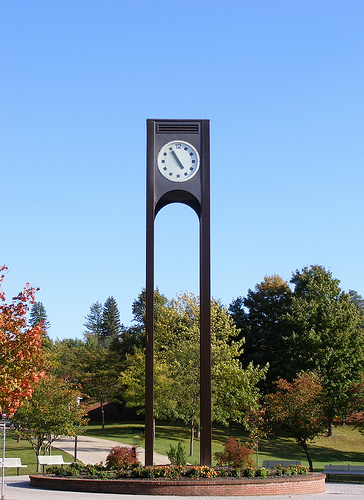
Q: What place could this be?
A: It is a park.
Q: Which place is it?
A: It is a park.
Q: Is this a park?
A: Yes, it is a park.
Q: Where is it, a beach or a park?
A: It is a park.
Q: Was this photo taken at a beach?
A: No, the picture was taken in a park.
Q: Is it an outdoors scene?
A: Yes, it is outdoors.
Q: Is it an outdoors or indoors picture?
A: It is outdoors.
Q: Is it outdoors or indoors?
A: It is outdoors.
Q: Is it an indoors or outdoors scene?
A: It is outdoors.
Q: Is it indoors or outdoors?
A: It is outdoors.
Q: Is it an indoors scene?
A: No, it is outdoors.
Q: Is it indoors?
A: No, it is outdoors.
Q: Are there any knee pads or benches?
A: Yes, there is a bench.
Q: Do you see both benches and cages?
A: No, there is a bench but no cages.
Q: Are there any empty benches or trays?
A: Yes, there is an empty bench.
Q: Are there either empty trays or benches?
A: Yes, there is an empty bench.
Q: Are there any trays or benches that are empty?
A: Yes, the bench is empty.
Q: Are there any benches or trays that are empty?
A: Yes, the bench is empty.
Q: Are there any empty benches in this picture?
A: Yes, there is an empty bench.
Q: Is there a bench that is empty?
A: Yes, there is a bench that is empty.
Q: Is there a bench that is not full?
A: Yes, there is a empty bench.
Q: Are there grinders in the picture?
A: No, there are no grinders.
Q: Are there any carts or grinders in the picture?
A: No, there are no grinders or carts.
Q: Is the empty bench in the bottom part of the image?
A: Yes, the bench is in the bottom of the image.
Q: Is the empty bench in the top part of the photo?
A: No, the bench is in the bottom of the image.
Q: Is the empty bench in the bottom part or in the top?
A: The bench is in the bottom of the image.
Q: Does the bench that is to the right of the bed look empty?
A: Yes, the bench is empty.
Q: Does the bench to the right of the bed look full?
A: No, the bench is empty.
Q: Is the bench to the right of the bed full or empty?
A: The bench is empty.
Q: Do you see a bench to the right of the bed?
A: Yes, there is a bench to the right of the bed.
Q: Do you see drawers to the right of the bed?
A: No, there is a bench to the right of the bed.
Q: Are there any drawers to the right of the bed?
A: No, there is a bench to the right of the bed.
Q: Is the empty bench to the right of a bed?
A: Yes, the bench is to the right of a bed.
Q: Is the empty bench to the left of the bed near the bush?
A: No, the bench is to the right of the bed.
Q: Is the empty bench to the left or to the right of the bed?
A: The bench is to the right of the bed.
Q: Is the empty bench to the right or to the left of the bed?
A: The bench is to the right of the bed.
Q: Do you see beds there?
A: Yes, there is a bed.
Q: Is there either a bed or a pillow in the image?
A: Yes, there is a bed.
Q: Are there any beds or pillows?
A: Yes, there is a bed.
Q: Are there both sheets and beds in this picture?
A: No, there is a bed but no sheets.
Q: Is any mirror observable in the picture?
A: No, there are no mirrors.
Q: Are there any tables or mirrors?
A: No, there are no mirrors or tables.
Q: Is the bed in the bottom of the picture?
A: Yes, the bed is in the bottom of the image.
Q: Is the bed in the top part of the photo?
A: No, the bed is in the bottom of the image.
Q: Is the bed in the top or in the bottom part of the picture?
A: The bed is in the bottom of the image.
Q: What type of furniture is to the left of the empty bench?
A: The piece of furniture is a bed.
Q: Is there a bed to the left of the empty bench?
A: Yes, there is a bed to the left of the bench.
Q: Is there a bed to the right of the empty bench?
A: No, the bed is to the left of the bench.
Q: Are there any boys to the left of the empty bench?
A: No, there is a bed to the left of the bench.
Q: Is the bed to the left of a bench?
A: Yes, the bed is to the left of a bench.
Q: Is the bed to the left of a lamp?
A: No, the bed is to the left of a bench.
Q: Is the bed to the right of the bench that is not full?
A: No, the bed is to the left of the bench.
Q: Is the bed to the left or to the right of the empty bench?
A: The bed is to the left of the bench.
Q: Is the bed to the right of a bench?
A: Yes, the bed is to the right of a bench.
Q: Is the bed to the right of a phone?
A: No, the bed is to the right of a bench.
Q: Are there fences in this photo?
A: No, there are no fences.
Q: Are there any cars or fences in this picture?
A: No, there are no fences or cars.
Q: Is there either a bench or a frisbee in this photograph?
A: Yes, there is a bench.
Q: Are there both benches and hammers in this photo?
A: No, there is a bench but no hammers.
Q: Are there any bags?
A: No, there are no bags.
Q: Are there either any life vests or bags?
A: No, there are no bags or life vests.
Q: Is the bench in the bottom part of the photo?
A: Yes, the bench is in the bottom of the image.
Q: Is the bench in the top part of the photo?
A: No, the bench is in the bottom of the image.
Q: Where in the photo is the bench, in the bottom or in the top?
A: The bench is in the bottom of the image.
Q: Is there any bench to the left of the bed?
A: Yes, there is a bench to the left of the bed.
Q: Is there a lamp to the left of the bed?
A: No, there is a bench to the left of the bed.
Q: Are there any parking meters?
A: No, there are no parking meters.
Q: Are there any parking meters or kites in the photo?
A: No, there are no parking meters or kites.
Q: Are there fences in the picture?
A: No, there are no fences.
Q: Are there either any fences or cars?
A: No, there are no fences or cars.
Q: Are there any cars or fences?
A: No, there are no fences or cars.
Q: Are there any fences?
A: No, there are no fences.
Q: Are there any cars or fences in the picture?
A: No, there are no fences or cars.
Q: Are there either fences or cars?
A: No, there are no fences or cars.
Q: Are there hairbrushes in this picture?
A: No, there are no hairbrushes.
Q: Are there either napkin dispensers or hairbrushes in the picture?
A: No, there are no hairbrushes or napkin dispensers.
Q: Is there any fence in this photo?
A: No, there are no fences.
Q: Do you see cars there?
A: No, there are no cars.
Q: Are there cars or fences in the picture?
A: No, there are no cars or fences.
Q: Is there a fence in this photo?
A: No, there are no fences.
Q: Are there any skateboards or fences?
A: No, there are no fences or skateboards.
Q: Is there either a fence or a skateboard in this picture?
A: No, there are no fences or skateboards.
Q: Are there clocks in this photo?
A: Yes, there is a clock.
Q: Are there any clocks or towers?
A: Yes, there is a clock.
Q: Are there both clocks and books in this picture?
A: No, there is a clock but no books.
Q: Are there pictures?
A: No, there are no pictures.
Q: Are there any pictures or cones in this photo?
A: No, there are no pictures or cones.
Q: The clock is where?
A: The clock is in the park.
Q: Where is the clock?
A: The clock is in the park.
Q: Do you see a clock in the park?
A: Yes, there is a clock in the park.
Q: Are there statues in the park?
A: No, there is a clock in the park.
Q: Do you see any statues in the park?
A: No, there is a clock in the park.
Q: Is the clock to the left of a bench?
A: Yes, the clock is to the left of a bench.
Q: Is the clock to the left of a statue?
A: No, the clock is to the left of a bench.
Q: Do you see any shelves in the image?
A: No, there are no shelves.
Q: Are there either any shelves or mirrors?
A: No, there are no shelves or mirrors.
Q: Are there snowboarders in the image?
A: No, there are no snowboarders.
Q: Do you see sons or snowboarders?
A: No, there are no snowboarders or sons.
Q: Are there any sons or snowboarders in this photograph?
A: No, there are no snowboarders or sons.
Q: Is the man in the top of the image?
A: Yes, the man is in the top of the image.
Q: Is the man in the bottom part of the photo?
A: No, the man is in the top of the image.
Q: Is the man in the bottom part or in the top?
A: The man is in the top of the image.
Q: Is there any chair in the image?
A: No, there are no chairs.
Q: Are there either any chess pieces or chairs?
A: No, there are no chairs or chess pieces.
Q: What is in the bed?
A: The flowers are in the bed.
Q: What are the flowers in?
A: The flowers are in the bed.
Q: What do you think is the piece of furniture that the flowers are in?
A: The piece of furniture is a bed.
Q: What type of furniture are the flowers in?
A: The flowers are in the bed.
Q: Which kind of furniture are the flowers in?
A: The flowers are in the bed.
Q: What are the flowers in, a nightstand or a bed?
A: The flowers are in a bed.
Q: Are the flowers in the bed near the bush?
A: Yes, the flowers are in the bed.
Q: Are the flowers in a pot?
A: No, the flowers are in the bed.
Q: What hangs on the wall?
A: The flowers hang on the wall.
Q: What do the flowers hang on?
A: The flowers hang on the wall.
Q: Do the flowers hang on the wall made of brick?
A: Yes, the flowers hang on the wall.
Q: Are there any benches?
A: Yes, there is a bench.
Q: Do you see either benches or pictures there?
A: Yes, there is a bench.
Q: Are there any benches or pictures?
A: Yes, there is a bench.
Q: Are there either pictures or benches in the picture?
A: Yes, there is a bench.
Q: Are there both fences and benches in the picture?
A: No, there is a bench but no fences.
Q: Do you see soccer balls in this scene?
A: No, there are no soccer balls.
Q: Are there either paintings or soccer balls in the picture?
A: No, there are no soccer balls or paintings.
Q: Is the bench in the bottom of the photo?
A: Yes, the bench is in the bottom of the image.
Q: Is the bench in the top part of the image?
A: No, the bench is in the bottom of the image.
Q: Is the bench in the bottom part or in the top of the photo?
A: The bench is in the bottom of the image.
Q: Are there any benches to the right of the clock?
A: Yes, there is a bench to the right of the clock.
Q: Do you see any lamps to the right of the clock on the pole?
A: No, there is a bench to the right of the clock.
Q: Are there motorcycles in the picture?
A: No, there are no motorcycles.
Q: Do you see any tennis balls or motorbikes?
A: No, there are no motorbikes or tennis balls.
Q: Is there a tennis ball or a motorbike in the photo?
A: No, there are no motorcycles or tennis balls.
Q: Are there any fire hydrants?
A: No, there are no fire hydrants.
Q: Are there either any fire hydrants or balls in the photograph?
A: No, there are no fire hydrants or balls.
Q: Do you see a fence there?
A: No, there are no fences.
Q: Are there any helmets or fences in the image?
A: No, there are no fences or helmets.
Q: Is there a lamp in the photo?
A: No, there are no lamps.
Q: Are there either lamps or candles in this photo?
A: No, there are no lamps or candles.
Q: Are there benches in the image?
A: Yes, there is a bench.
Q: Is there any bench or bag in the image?
A: Yes, there is a bench.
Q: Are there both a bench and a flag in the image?
A: No, there is a bench but no flags.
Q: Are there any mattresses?
A: No, there are no mattresses.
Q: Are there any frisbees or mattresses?
A: No, there are no mattresses or frisbees.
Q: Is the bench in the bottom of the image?
A: Yes, the bench is in the bottom of the image.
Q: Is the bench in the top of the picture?
A: No, the bench is in the bottom of the image.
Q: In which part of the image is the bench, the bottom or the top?
A: The bench is in the bottom of the image.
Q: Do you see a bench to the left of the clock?
A: Yes, there is a bench to the left of the clock.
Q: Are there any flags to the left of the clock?
A: No, there is a bench to the left of the clock.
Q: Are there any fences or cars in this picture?
A: No, there are no fences or cars.